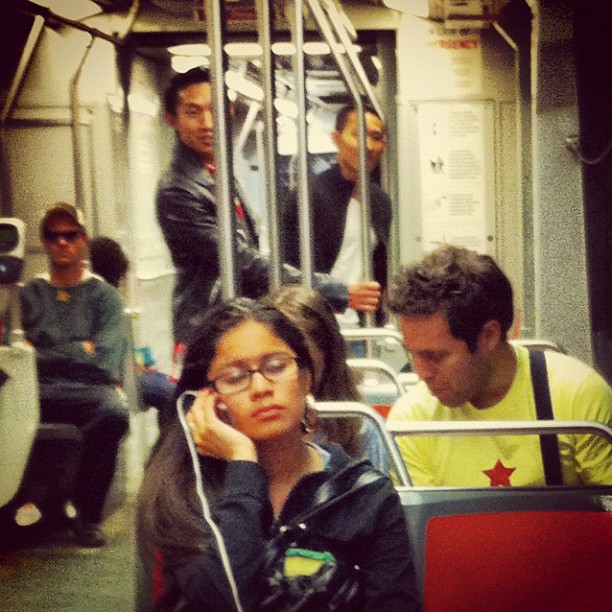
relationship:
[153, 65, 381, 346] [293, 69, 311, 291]
man holding onto pole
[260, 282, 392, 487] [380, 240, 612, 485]
person sitting next to man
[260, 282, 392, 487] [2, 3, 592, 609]
person riding subway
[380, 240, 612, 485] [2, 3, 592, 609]
man riding subway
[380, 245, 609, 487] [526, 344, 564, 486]
man carrying bag